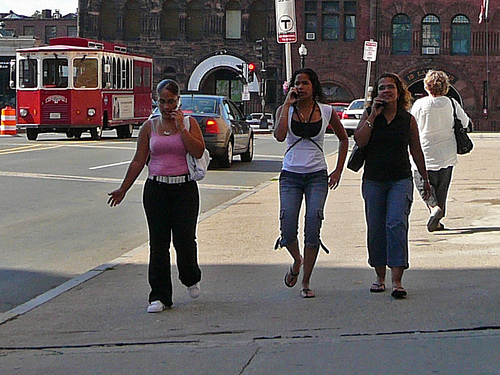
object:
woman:
[104, 78, 213, 315]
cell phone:
[172, 97, 184, 112]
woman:
[273, 66, 346, 299]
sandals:
[281, 254, 303, 288]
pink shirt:
[149, 115, 188, 177]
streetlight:
[247, 61, 254, 71]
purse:
[346, 143, 367, 173]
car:
[144, 91, 254, 165]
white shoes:
[187, 284, 200, 300]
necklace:
[157, 116, 177, 137]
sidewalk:
[3, 131, 497, 369]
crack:
[238, 344, 266, 374]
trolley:
[9, 35, 154, 141]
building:
[0, 1, 499, 135]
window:
[224, 9, 241, 39]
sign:
[275, 2, 296, 44]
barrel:
[1, 105, 15, 137]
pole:
[286, 43, 292, 86]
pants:
[142, 173, 203, 306]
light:
[204, 118, 221, 135]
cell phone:
[291, 83, 299, 98]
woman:
[353, 70, 435, 299]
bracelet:
[420, 178, 432, 185]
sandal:
[300, 287, 314, 298]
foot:
[298, 285, 314, 300]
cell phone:
[374, 93, 381, 114]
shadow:
[434, 226, 499, 234]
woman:
[410, 69, 471, 233]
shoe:
[426, 206, 444, 233]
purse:
[450, 96, 474, 156]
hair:
[291, 64, 328, 103]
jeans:
[275, 169, 330, 255]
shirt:
[283, 100, 332, 174]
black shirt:
[364, 101, 412, 179]